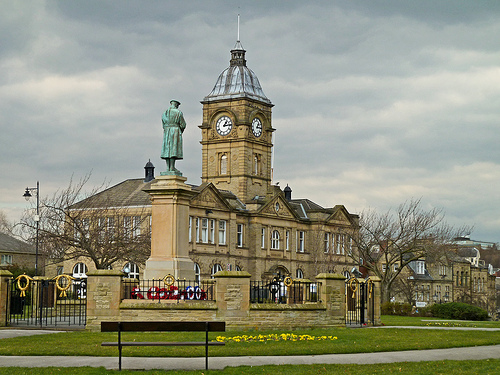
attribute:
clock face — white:
[213, 115, 235, 136]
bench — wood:
[103, 314, 240, 369]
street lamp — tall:
[22, 181, 41, 278]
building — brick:
[22, 13, 385, 314]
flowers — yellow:
[210, 329, 339, 346]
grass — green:
[165, 314, 460, 368]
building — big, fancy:
[54, 16, 361, 333]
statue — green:
[159, 99, 184, 175]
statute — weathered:
[138, 95, 243, 192]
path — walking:
[0, 343, 497, 369]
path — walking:
[367, 325, 498, 332]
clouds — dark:
[2, 8, 497, 238]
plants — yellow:
[213, 332, 340, 342]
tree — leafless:
[13, 173, 148, 269]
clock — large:
[249, 118, 265, 137]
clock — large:
[211, 115, 232, 135]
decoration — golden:
[53, 273, 73, 299]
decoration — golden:
[13, 273, 31, 300]